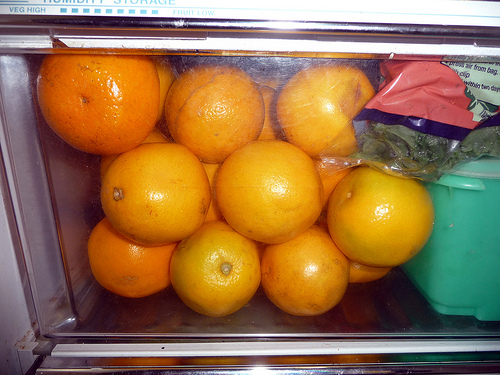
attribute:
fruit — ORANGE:
[38, 53, 156, 149]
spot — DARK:
[75, 88, 95, 112]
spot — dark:
[71, 90, 97, 110]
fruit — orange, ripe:
[34, 51, 163, 154]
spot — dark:
[77, 99, 94, 111]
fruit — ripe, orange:
[94, 148, 209, 241]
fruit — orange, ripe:
[82, 219, 170, 297]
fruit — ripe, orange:
[169, 219, 259, 320]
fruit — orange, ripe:
[263, 240, 348, 316]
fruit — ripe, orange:
[218, 135, 320, 238]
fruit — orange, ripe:
[325, 162, 433, 272]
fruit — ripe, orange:
[279, 60, 369, 160]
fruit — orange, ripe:
[348, 256, 390, 284]